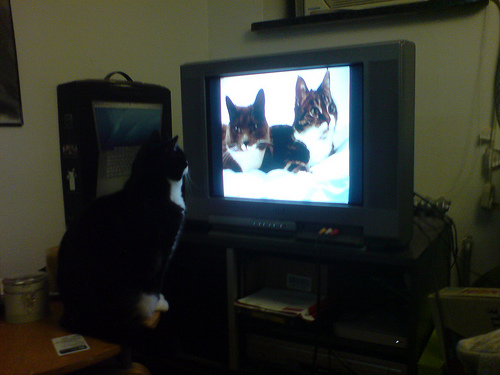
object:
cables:
[319, 227, 334, 236]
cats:
[220, 88, 273, 173]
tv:
[178, 39, 416, 258]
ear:
[254, 87, 266, 108]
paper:
[50, 331, 92, 356]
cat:
[37, 129, 190, 374]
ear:
[293, 75, 307, 96]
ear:
[319, 67, 332, 89]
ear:
[225, 95, 238, 115]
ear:
[164, 135, 179, 153]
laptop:
[92, 100, 163, 198]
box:
[57, 79, 172, 228]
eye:
[231, 125, 241, 133]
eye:
[308, 105, 323, 118]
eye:
[326, 102, 338, 114]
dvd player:
[330, 324, 414, 347]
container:
[2, 274, 47, 325]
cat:
[270, 67, 337, 173]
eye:
[249, 121, 258, 131]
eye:
[327, 100, 336, 115]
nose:
[240, 131, 250, 145]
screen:
[206, 64, 366, 206]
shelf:
[250, 1, 490, 36]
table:
[0, 301, 160, 373]